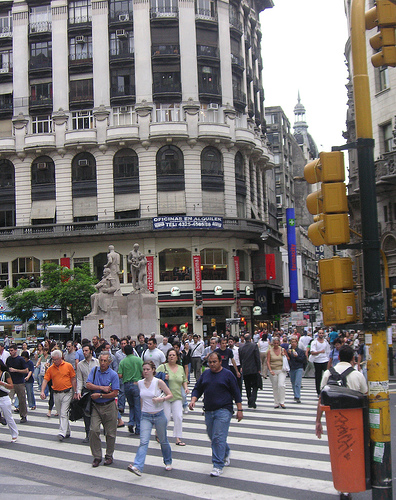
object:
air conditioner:
[74, 33, 84, 44]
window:
[66, 31, 92, 65]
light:
[301, 150, 349, 244]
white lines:
[251, 436, 320, 455]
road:
[24, 432, 257, 498]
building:
[0, 1, 281, 338]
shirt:
[137, 376, 164, 411]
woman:
[122, 354, 176, 477]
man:
[227, 336, 243, 393]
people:
[74, 344, 101, 445]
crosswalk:
[0, 392, 330, 498]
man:
[189, 333, 204, 382]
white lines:
[34, 458, 206, 495]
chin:
[211, 368, 216, 370]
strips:
[254, 402, 302, 476]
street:
[46, 449, 296, 481]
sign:
[152, 214, 224, 231]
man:
[189, 351, 243, 475]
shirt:
[190, 366, 240, 410]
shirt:
[155, 360, 188, 402]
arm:
[84, 371, 104, 392]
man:
[84, 349, 120, 467]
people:
[152, 348, 190, 447]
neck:
[210, 364, 222, 373]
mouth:
[209, 364, 216, 369]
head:
[207, 354, 221, 372]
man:
[38, 344, 77, 440]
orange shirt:
[43, 361, 74, 392]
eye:
[214, 360, 217, 364]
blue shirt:
[88, 367, 120, 403]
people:
[125, 355, 173, 478]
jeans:
[203, 407, 230, 467]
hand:
[189, 401, 196, 410]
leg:
[211, 410, 232, 467]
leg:
[205, 410, 230, 460]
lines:
[238, 470, 310, 493]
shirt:
[213, 347, 234, 369]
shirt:
[319, 359, 368, 412]